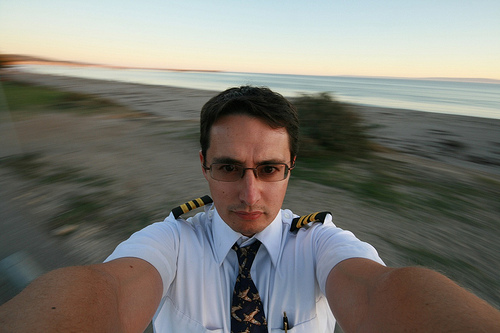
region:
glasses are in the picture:
[201, 158, 298, 183]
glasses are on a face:
[198, 85, 292, 229]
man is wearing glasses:
[2, 84, 414, 329]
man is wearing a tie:
[142, 84, 346, 331]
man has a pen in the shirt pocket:
[125, 84, 330, 331]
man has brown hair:
[147, 82, 334, 330]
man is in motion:
[1, 83, 498, 330]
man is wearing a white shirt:
[111, 85, 354, 331]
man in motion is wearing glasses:
[131, 84, 368, 330]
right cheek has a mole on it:
[201, 98, 289, 229]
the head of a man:
[192, 83, 299, 235]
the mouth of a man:
[225, 204, 269, 221]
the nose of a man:
[232, 164, 264, 209]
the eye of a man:
[216, 157, 243, 177]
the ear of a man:
[195, 146, 210, 183]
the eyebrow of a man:
[210, 151, 248, 168]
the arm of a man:
[0, 211, 187, 331]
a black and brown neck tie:
[227, 235, 270, 332]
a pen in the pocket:
[278, 304, 294, 331]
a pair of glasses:
[196, 156, 297, 183]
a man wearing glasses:
[177, 91, 322, 233]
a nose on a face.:
[235, 161, 271, 212]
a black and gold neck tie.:
[227, 235, 279, 332]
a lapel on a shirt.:
[241, 191, 290, 274]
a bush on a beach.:
[272, 78, 391, 193]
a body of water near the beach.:
[7, 48, 498, 121]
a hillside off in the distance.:
[0, 41, 127, 71]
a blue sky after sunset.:
[0, 1, 498, 76]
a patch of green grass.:
[0, 72, 169, 140]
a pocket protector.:
[264, 306, 301, 332]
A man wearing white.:
[118, 7, 334, 324]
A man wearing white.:
[138, 134, 273, 330]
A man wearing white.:
[181, 181, 281, 326]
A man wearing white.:
[175, 76, 315, 313]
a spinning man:
[2, 85, 498, 329]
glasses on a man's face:
[200, 160, 292, 181]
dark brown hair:
[200, 85, 297, 170]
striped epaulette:
[172, 193, 212, 218]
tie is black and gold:
[226, 240, 271, 332]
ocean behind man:
[0, 56, 499, 120]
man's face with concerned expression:
[197, 118, 299, 232]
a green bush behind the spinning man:
[290, 92, 372, 172]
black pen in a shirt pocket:
[282, 311, 289, 331]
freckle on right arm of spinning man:
[50, 304, 57, 309]